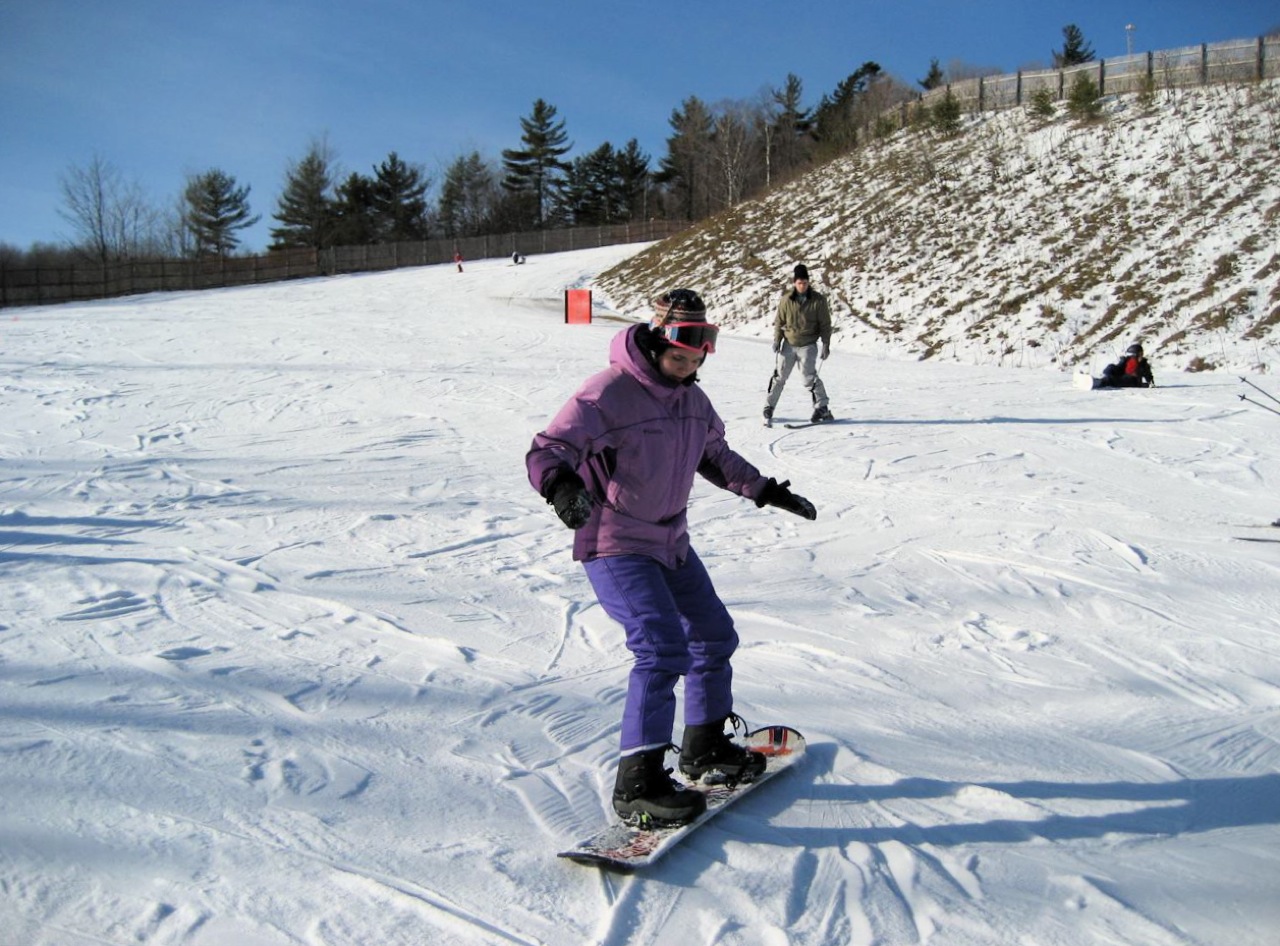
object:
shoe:
[613, 742, 706, 827]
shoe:
[678, 711, 766, 784]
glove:
[756, 477, 817, 519]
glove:
[541, 461, 593, 529]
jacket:
[775, 285, 832, 347]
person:
[1092, 344, 1155, 390]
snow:
[0, 239, 1280, 946]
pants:
[582, 544, 739, 756]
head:
[648, 289, 719, 382]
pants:
[764, 344, 828, 409]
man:
[763, 264, 833, 429]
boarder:
[526, 289, 818, 868]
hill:
[576, 15, 1280, 369]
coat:
[526, 323, 768, 571]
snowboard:
[557, 726, 806, 869]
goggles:
[658, 325, 717, 351]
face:
[659, 348, 705, 383]